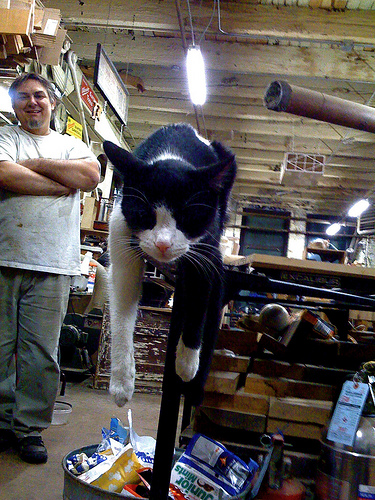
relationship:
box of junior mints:
[54, 420, 334, 500] [76, 418, 269, 495]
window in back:
[229, 199, 299, 264] [228, 198, 374, 257]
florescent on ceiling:
[171, 42, 221, 112] [79, 5, 370, 150]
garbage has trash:
[54, 420, 334, 500] [76, 418, 269, 495]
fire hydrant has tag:
[311, 353, 372, 499] [316, 370, 372, 457]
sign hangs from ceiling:
[83, 41, 137, 131] [79, 5, 370, 150]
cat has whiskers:
[87, 112, 243, 415] [86, 236, 231, 277]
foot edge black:
[174, 291, 211, 382] [183, 283, 208, 353]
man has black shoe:
[1, 57, 108, 472] [2, 420, 56, 476]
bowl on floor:
[50, 396, 78, 428] [43, 369, 124, 443]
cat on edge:
[87, 112, 243, 415] [162, 250, 374, 408]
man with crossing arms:
[1, 57, 108, 472] [1, 139, 107, 204]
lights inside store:
[171, 42, 221, 112] [10, 8, 371, 483]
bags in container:
[76, 418, 269, 495] [54, 420, 334, 500]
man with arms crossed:
[1, 57, 108, 472] [1, 139, 107, 204]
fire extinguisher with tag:
[311, 353, 372, 499] [316, 370, 372, 457]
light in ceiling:
[171, 42, 221, 112] [79, 5, 370, 150]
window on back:
[229, 199, 299, 264] [228, 198, 374, 257]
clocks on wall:
[48, 100, 78, 134] [41, 53, 132, 148]